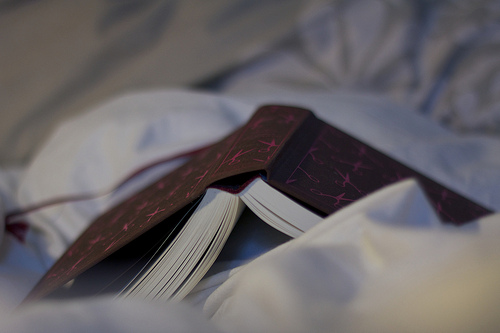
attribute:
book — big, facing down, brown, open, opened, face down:
[12, 103, 496, 307]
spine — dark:
[205, 105, 314, 194]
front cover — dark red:
[16, 124, 245, 309]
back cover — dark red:
[268, 118, 497, 226]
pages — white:
[89, 177, 324, 308]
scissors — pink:
[223, 148, 253, 167]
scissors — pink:
[258, 137, 280, 152]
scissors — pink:
[311, 187, 357, 208]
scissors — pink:
[333, 166, 366, 195]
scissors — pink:
[332, 154, 376, 177]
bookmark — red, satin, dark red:
[4, 144, 213, 244]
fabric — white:
[1, 1, 499, 333]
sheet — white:
[1, 1, 499, 333]